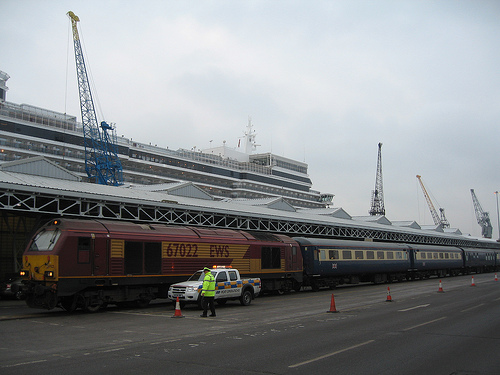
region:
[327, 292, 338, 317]
the cone is orange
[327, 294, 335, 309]
the cone is orange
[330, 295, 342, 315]
the cone is orange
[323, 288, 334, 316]
the cone is orange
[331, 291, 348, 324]
the cone is orange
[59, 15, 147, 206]
crane is blue and yellow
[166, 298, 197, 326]
caution cone has white stripe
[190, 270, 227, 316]
safety jacket is neon yellow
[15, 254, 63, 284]
headlights on the train are on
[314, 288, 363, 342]
safety cone is orange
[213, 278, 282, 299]
blue and yellow checkers on the truck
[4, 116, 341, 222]
cruise boat in port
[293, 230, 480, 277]
yellow stripe on two train cars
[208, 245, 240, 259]
EWS written on side of train car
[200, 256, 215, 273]
man wearing safety hat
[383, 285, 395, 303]
the cone is orange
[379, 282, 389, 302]
the cone is orange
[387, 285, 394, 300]
the cone is orange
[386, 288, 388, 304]
the cone is orange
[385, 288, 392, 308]
the cone is orange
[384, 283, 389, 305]
the cone is orange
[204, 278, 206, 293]
the vest is green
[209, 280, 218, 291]
the vest is green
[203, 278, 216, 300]
the vest is green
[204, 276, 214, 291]
the vest is green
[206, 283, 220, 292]
the vest is green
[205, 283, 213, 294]
the vest is green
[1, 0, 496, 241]
a white sky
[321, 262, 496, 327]
a row of orange cones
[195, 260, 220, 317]
a person with green jacket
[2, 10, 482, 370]
a scene outside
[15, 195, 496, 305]
a train that is red and blue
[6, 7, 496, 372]
a scene during the day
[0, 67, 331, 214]
a large ship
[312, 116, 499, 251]
a row of canes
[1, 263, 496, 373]
a gray road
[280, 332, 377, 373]
a white line painted on the road